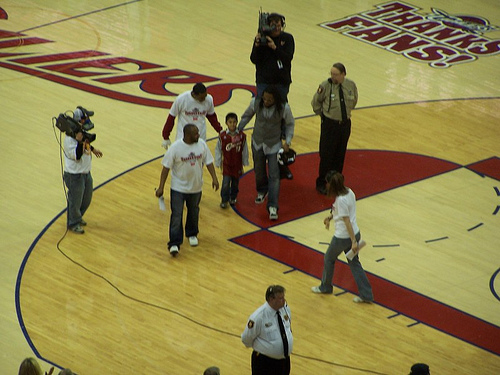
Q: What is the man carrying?
A: A white paper.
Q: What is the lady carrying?
A: A white paper.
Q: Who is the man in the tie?
A: A security guard.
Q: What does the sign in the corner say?
A: Thanks fans.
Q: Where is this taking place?
A: A basketball court.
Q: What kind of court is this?
A: Basketball court.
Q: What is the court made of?
A: Wood.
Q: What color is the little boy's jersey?
A: Red.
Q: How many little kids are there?
A: One.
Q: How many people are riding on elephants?
A: Zero.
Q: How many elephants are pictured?
A: Zero.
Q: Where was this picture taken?
A: Basketball court.